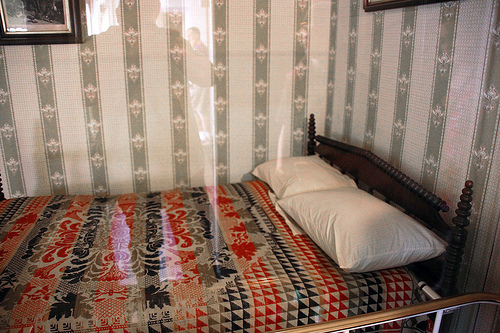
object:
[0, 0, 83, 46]
frame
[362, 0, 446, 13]
frame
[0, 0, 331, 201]
wallpaper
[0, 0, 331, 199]
wall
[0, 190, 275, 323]
pattern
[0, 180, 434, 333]
bedspread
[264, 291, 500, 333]
frame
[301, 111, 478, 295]
olympic sign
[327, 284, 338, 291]
triangle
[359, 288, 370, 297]
triangle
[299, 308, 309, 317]
triangle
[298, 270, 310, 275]
triangle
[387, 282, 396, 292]
triangle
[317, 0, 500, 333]
wallpaper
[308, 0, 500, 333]
wall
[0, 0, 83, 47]
picture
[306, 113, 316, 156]
post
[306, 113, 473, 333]
bed frame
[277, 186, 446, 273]
pillow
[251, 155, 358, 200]
pillow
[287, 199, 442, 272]
wrinkles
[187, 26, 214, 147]
man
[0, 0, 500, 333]
drape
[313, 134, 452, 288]
headboard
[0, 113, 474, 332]
bed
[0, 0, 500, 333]
design